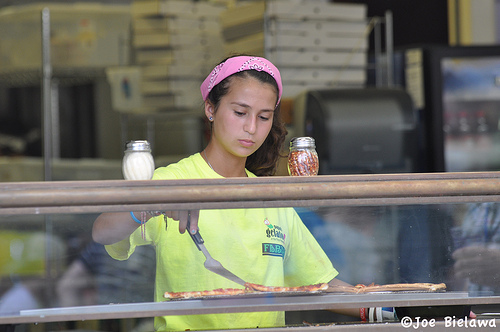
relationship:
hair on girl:
[203, 62, 289, 175] [94, 56, 386, 331]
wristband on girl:
[361, 309, 384, 325] [94, 56, 386, 331]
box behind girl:
[240, 48, 368, 68] [94, 56, 386, 331]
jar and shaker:
[121, 138, 155, 179] [286, 136, 322, 178]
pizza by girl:
[162, 281, 326, 301] [94, 56, 386, 331]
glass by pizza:
[1, 204, 499, 316] [162, 281, 326, 301]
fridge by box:
[390, 41, 498, 299] [240, 48, 368, 68]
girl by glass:
[94, 56, 386, 331] [1, 204, 499, 316]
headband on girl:
[197, 56, 283, 111] [94, 56, 386, 331]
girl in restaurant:
[94, 56, 386, 331] [2, 0, 498, 331]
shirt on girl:
[105, 152, 336, 323] [94, 56, 386, 331]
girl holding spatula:
[94, 56, 386, 331] [178, 219, 260, 290]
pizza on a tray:
[162, 281, 326, 301] [174, 290, 329, 298]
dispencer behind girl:
[289, 85, 427, 181] [94, 56, 386, 331]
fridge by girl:
[390, 41, 498, 299] [94, 56, 386, 331]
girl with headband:
[94, 56, 386, 331] [197, 56, 283, 111]